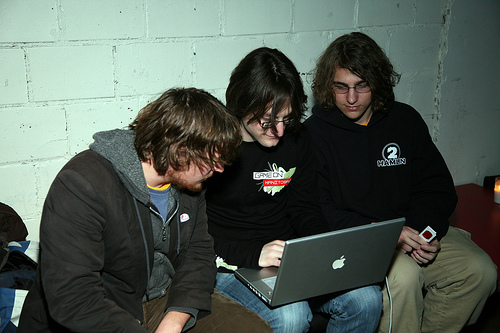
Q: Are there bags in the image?
A: No, there are no bags.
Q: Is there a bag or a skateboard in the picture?
A: No, there are no bags or skateboards.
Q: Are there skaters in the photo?
A: No, there are no skaters.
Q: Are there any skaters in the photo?
A: No, there are no skaters.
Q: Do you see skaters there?
A: No, there are no skaters.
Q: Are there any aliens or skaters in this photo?
A: No, there are no skaters or aliens.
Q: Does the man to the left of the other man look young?
A: Yes, the man is young.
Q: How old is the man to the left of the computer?
A: The man is young.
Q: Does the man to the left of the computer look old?
A: No, the man is young.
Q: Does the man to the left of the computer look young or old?
A: The man is young.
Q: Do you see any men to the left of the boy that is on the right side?
A: Yes, there is a man to the left of the boy.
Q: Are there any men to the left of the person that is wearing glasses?
A: Yes, there is a man to the left of the boy.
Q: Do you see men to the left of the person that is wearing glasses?
A: Yes, there is a man to the left of the boy.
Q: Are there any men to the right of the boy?
A: No, the man is to the left of the boy.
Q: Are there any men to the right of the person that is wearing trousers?
A: No, the man is to the left of the boy.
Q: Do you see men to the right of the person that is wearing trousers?
A: No, the man is to the left of the boy.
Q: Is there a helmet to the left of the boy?
A: No, there is a man to the left of the boy.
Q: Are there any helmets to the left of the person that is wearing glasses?
A: No, there is a man to the left of the boy.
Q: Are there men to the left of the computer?
A: Yes, there is a man to the left of the computer.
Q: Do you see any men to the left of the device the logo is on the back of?
A: Yes, there is a man to the left of the computer.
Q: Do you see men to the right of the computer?
A: No, the man is to the left of the computer.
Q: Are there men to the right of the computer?
A: No, the man is to the left of the computer.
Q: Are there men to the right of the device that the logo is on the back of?
A: No, the man is to the left of the computer.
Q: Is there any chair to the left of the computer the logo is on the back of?
A: No, there is a man to the left of the computer.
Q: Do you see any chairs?
A: No, there are no chairs.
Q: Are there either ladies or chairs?
A: No, there are no chairs or ladies.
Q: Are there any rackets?
A: No, there are no rackets.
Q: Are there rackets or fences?
A: No, there are no rackets or fences.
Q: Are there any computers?
A: Yes, there is a computer.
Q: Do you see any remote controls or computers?
A: Yes, there is a computer.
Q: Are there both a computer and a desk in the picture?
A: No, there is a computer but no desks.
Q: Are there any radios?
A: No, there are no radios.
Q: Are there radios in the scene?
A: No, there are no radios.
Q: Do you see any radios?
A: No, there are no radios.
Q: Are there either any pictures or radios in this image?
A: No, there are no radios or pictures.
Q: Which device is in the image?
A: The device is a computer.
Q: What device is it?
A: The device is a computer.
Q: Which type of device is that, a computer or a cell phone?
A: This is a computer.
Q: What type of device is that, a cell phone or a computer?
A: This is a computer.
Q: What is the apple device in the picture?
A: The device is a computer.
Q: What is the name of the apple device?
A: The device is a computer.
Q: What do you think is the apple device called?
A: The device is a computer.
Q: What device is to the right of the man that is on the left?
A: The device is a computer.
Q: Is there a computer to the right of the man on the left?
A: Yes, there is a computer to the right of the man.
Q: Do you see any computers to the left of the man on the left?
A: No, the computer is to the right of the man.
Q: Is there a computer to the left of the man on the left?
A: No, the computer is to the right of the man.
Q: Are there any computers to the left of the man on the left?
A: No, the computer is to the right of the man.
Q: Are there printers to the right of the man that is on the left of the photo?
A: No, there is a computer to the right of the man.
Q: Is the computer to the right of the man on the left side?
A: Yes, the computer is to the right of the man.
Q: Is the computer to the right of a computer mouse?
A: No, the computer is to the right of the man.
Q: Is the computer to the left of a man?
A: No, the computer is to the right of a man.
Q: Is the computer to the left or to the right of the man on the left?
A: The computer is to the right of the man.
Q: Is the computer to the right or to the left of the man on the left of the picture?
A: The computer is to the right of the man.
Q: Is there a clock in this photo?
A: No, there are no clocks.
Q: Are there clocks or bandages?
A: No, there are no clocks or bandages.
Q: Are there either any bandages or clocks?
A: No, there are no clocks or bandages.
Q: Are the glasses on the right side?
A: Yes, the glasses are on the right of the image.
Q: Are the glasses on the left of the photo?
A: No, the glasses are on the right of the image.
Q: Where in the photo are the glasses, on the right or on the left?
A: The glasses are on the right of the image.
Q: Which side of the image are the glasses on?
A: The glasses are on the right of the image.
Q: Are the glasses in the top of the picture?
A: Yes, the glasses are in the top of the image.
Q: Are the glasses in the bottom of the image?
A: No, the glasses are in the top of the image.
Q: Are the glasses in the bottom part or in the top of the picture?
A: The glasses are in the top of the image.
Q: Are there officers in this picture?
A: No, there are no officers.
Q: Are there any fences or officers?
A: No, there are no officers or fences.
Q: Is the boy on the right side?
A: Yes, the boy is on the right of the image.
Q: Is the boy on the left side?
A: No, the boy is on the right of the image.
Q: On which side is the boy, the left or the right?
A: The boy is on the right of the image.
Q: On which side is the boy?
A: The boy is on the right of the image.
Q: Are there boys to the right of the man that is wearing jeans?
A: Yes, there is a boy to the right of the man.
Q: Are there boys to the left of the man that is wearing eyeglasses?
A: No, the boy is to the right of the man.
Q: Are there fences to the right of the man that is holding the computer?
A: No, there is a boy to the right of the man.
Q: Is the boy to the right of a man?
A: Yes, the boy is to the right of a man.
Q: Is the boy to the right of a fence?
A: No, the boy is to the right of a man.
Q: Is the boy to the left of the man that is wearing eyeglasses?
A: No, the boy is to the right of the man.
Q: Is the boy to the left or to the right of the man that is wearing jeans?
A: The boy is to the right of the man.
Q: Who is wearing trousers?
A: The boy is wearing trousers.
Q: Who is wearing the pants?
A: The boy is wearing trousers.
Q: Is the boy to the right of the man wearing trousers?
A: Yes, the boy is wearing trousers.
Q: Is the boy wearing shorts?
A: No, the boy is wearing trousers.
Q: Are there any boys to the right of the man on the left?
A: Yes, there is a boy to the right of the man.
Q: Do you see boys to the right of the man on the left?
A: Yes, there is a boy to the right of the man.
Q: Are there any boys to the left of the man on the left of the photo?
A: No, the boy is to the right of the man.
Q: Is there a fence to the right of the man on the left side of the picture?
A: No, there is a boy to the right of the man.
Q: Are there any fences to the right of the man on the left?
A: No, there is a boy to the right of the man.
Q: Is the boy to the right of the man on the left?
A: Yes, the boy is to the right of the man.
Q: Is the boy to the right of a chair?
A: No, the boy is to the right of the man.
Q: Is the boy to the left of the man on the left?
A: No, the boy is to the right of the man.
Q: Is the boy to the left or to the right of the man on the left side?
A: The boy is to the right of the man.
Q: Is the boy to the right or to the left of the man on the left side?
A: The boy is to the right of the man.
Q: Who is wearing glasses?
A: The boy is wearing glasses.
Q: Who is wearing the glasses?
A: The boy is wearing glasses.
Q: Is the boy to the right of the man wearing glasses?
A: Yes, the boy is wearing glasses.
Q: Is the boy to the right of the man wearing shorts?
A: No, the boy is wearing glasses.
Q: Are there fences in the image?
A: No, there are no fences.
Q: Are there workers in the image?
A: No, there are no workers.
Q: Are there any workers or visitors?
A: No, there are no workers or visitors.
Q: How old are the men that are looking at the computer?
A: The men are young.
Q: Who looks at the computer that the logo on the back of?
A: The men look at the computer.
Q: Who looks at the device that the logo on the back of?
A: The men look at the computer.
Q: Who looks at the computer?
A: The men look at the computer.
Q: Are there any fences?
A: No, there are no fences.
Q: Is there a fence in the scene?
A: No, there are no fences.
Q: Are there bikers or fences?
A: No, there are no fences or bikers.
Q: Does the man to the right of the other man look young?
A: Yes, the man is young.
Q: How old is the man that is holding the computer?
A: The man is young.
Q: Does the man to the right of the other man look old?
A: No, the man is young.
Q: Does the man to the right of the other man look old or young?
A: The man is young.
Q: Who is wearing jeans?
A: The man is wearing jeans.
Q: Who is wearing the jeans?
A: The man is wearing jeans.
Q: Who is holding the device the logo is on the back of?
A: The man is holding the computer.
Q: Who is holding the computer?
A: The man is holding the computer.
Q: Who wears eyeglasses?
A: The man wears eyeglasses.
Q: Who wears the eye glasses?
A: The man wears eyeglasses.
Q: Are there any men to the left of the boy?
A: Yes, there is a man to the left of the boy.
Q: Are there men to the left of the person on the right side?
A: Yes, there is a man to the left of the boy.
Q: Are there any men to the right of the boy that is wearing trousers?
A: No, the man is to the left of the boy.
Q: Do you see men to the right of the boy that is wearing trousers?
A: No, the man is to the left of the boy.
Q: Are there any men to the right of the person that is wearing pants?
A: No, the man is to the left of the boy.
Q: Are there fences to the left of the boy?
A: No, there is a man to the left of the boy.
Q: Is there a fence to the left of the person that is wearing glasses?
A: No, there is a man to the left of the boy.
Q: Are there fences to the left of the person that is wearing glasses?
A: No, there is a man to the left of the boy.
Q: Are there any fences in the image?
A: No, there are no fences.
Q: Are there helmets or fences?
A: No, there are no fences or helmets.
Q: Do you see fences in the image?
A: No, there are no fences.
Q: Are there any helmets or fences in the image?
A: No, there are no fences or helmets.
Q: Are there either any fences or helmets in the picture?
A: No, there are no fences or helmets.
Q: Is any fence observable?
A: No, there are no fences.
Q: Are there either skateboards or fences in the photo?
A: No, there are no fences or skateboards.